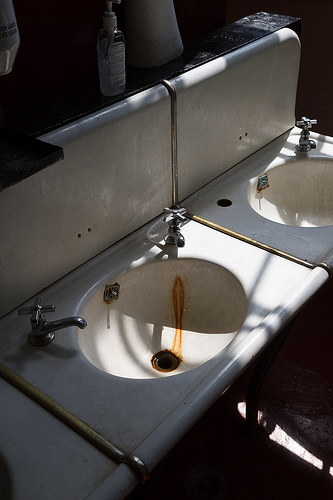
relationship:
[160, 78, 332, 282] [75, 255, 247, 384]
metal strip on bowl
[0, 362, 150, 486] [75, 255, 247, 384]
metal strip on bowl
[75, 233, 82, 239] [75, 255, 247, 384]
hole on bowl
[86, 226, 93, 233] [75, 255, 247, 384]
hole on bowl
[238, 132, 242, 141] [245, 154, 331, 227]
holes on bowl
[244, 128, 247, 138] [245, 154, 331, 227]
holes on bowl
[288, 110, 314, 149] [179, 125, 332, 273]
handle on sink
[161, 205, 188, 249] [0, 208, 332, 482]
faucet on sink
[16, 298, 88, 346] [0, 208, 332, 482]
faucet on sink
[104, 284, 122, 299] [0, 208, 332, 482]
grate on sink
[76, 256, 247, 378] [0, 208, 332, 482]
bowl on sink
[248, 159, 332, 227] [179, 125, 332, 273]
bowl on sink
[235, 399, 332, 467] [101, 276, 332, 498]
sunlight on ground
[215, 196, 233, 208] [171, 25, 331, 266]
hole in sink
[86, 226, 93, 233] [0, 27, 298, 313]
hole in back splash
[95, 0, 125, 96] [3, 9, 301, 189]
bottle on top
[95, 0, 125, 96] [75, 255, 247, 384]
bottle on bowl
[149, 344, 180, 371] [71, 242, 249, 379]
drain in sink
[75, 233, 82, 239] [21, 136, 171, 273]
hole in wall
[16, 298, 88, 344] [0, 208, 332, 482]
faucet on left side of sink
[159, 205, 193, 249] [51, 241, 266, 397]
faucet on right side of sink